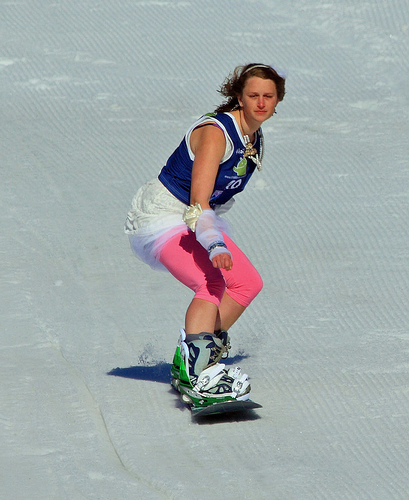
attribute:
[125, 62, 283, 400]
woman — snowboarding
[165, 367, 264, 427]
snowboard — white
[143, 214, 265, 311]
leggings — pink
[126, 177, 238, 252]
skirt — white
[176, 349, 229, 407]
bindings — green, white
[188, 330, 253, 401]
boot — grey, blue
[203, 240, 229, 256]
bracelet — silver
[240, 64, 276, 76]
headband — white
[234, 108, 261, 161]
necklace — brown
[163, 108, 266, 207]
shirt — blue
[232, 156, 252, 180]
character — green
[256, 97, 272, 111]
nose — red